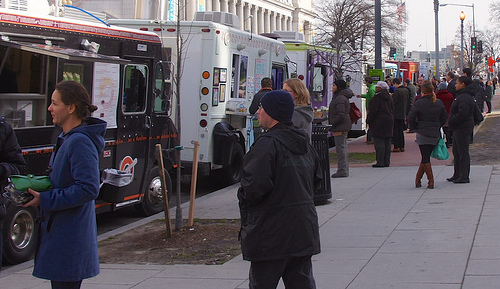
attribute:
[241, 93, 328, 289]
man — close, older, standing, here, looking, outdoors, visable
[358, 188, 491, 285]
sidewalk — close, brown, red, white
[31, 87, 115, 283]
woman — standing, visable, still, talking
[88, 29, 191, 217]
truck — red, orange, parked, sitting, big, black, here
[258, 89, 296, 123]
cap — blue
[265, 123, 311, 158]
hoodie — black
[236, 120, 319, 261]
jacket — black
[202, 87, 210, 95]
light — red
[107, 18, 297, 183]
food truck — white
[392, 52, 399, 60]
light — green